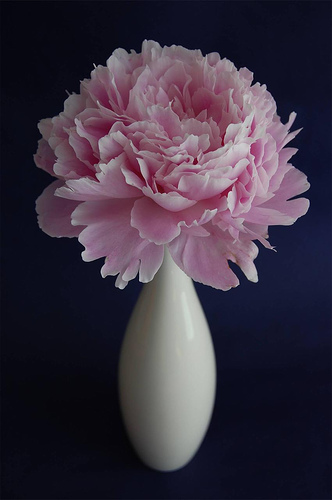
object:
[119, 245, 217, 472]
jug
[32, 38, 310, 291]
flower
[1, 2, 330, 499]
room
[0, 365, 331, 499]
table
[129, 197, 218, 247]
petal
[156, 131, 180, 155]
center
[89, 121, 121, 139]
shadow